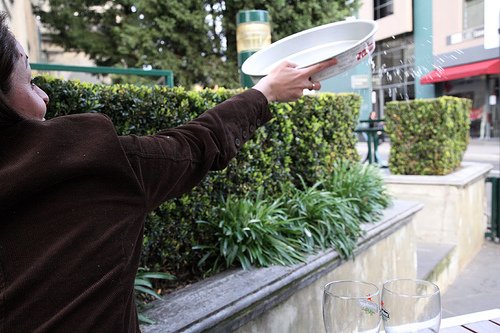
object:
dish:
[242, 29, 380, 82]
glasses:
[319, 278, 385, 332]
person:
[0, 12, 335, 333]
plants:
[326, 160, 386, 221]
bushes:
[273, 94, 359, 191]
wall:
[223, 207, 424, 333]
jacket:
[0, 90, 273, 333]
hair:
[0, 25, 26, 87]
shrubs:
[295, 178, 370, 260]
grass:
[405, 109, 443, 169]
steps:
[411, 243, 466, 297]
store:
[418, 59, 499, 139]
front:
[435, 75, 497, 139]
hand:
[260, 60, 339, 104]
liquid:
[375, 31, 456, 102]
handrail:
[28, 61, 174, 92]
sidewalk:
[356, 137, 497, 167]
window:
[372, 65, 406, 88]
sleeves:
[127, 88, 274, 211]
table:
[359, 306, 500, 333]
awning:
[421, 58, 499, 82]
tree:
[48, 0, 238, 85]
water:
[425, 34, 468, 100]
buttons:
[234, 138, 241, 146]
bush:
[381, 96, 473, 172]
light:
[234, 11, 270, 53]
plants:
[197, 192, 310, 274]